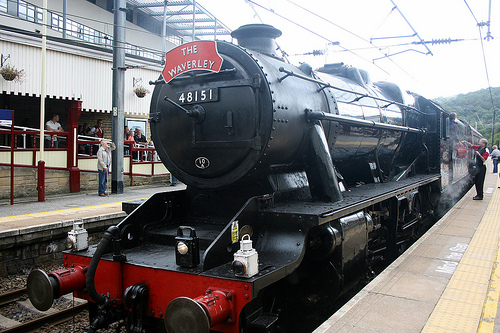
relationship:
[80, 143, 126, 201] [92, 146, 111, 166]
man wears jacket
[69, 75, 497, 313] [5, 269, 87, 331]
train on track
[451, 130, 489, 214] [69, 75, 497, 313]
man near train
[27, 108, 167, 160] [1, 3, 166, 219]
people on platform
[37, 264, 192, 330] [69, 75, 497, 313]
bumper on train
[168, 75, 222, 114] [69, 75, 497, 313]
number on train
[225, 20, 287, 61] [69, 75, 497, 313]
chimney on train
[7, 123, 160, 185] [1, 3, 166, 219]
ramp on platform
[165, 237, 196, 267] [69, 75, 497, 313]
light on train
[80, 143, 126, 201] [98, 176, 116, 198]
man holds cane